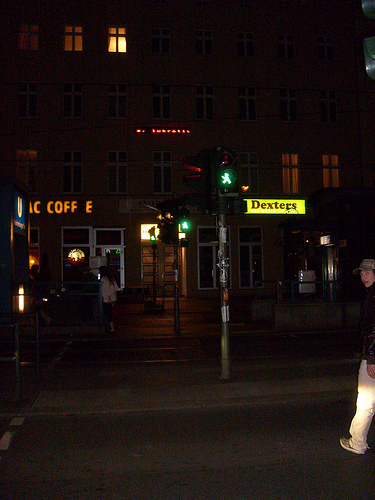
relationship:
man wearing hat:
[332, 257, 374, 457] [353, 256, 371, 275]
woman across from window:
[95, 265, 119, 332] [236, 227, 267, 295]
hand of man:
[366, 361, 374, 381] [332, 257, 374, 457]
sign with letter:
[22, 192, 99, 227] [76, 202, 85, 217]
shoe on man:
[336, 434, 369, 455] [332, 254, 362, 456]